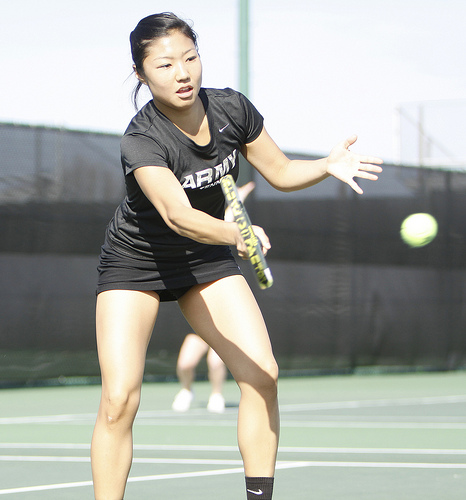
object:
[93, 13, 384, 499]
person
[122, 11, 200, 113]
hair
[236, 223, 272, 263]
hand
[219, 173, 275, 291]
racket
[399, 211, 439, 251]
ball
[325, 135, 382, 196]
hand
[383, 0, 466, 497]
left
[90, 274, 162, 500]
leg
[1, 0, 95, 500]
right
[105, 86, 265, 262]
shirt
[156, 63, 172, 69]
eye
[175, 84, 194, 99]
mouth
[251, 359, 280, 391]
knee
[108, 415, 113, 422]
scar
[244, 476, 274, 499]
sock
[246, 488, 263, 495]
logo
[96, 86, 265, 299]
uniform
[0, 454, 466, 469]
line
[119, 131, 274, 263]
arm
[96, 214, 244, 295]
skirt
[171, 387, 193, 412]
shoes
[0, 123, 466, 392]
fence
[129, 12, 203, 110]
head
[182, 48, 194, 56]
eyebrow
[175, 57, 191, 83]
nose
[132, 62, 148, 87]
ear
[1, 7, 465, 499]
air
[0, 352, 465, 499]
court